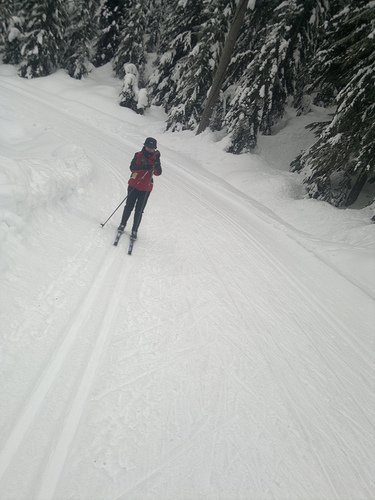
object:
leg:
[133, 190, 150, 233]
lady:
[116, 135, 162, 240]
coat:
[128, 152, 161, 191]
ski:
[114, 228, 124, 248]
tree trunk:
[192, 2, 249, 136]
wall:
[257, 75, 329, 167]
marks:
[0, 257, 128, 500]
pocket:
[130, 170, 138, 179]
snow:
[0, 64, 375, 500]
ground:
[0, 65, 375, 499]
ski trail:
[0, 59, 375, 500]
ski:
[126, 232, 137, 256]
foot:
[130, 230, 137, 241]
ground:
[240, 77, 273, 108]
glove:
[142, 162, 153, 170]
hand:
[155, 158, 159, 164]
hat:
[145, 135, 157, 150]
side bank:
[3, 121, 91, 210]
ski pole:
[98, 158, 159, 231]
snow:
[126, 64, 148, 104]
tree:
[118, 57, 149, 113]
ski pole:
[132, 169, 156, 239]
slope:
[0, 63, 373, 500]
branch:
[120, 61, 138, 107]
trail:
[2, 65, 375, 496]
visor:
[143, 142, 157, 148]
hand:
[153, 151, 161, 161]